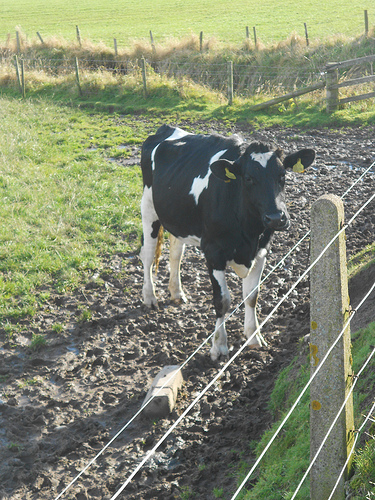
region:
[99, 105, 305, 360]
This is a cow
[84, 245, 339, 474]
A fence for the cow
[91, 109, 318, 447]
This cow is black and white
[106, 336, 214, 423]
A plank of wood on the ground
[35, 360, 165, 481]
The ground is dirty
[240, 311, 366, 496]
Grass is near the fence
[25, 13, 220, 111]
Hay by the fence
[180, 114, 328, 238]
The cow is looking foward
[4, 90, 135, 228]
The grass has not been cut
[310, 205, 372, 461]
Wires sticking out of the fence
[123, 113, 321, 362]
Cow inside a barnyard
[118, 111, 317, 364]
Cow is black and white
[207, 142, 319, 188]
Ears are round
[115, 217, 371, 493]
Wires are metal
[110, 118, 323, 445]
Cow stand on the mud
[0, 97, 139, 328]
Barnyard has patch green grass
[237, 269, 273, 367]
Leg is white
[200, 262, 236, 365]
Leg is white and black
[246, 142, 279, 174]
White spot on head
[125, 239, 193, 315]
Back legs are white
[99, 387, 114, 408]
a step in the mud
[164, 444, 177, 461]
a step in the mud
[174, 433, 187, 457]
a step in the mud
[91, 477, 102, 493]
a step in the mud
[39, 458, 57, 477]
a step in the mud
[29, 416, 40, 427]
a step in the mud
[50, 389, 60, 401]
a step in the mud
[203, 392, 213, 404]
a step in the mud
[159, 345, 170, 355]
a step in the mud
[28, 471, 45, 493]
a step in the mud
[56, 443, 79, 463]
a step in the mud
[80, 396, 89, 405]
a step in the mud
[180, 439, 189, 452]
a step in the mud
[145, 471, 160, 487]
a step in the mud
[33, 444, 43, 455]
a step in the mud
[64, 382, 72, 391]
a step in the mud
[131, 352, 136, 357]
a step in the mud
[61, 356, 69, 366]
a step in the mud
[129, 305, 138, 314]
a step in the mud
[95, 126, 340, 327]
a black and white cow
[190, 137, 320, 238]
a cow with yellow tags attached to its ears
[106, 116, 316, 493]
a cow standing in the mud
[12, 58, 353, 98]
a wire fence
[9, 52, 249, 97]
wooden fence post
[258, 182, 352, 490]
a concrete fence post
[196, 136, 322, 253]
a cow eating grass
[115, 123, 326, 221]
the back bone of a cow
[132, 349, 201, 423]
a concrete block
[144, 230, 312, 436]
a wire cable fence